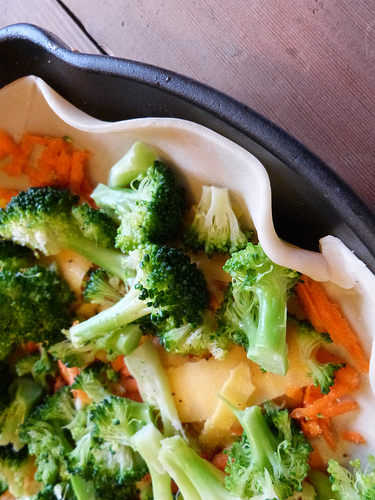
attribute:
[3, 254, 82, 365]
broccoli spear — green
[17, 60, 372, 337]
dish — white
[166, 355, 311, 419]
cheese — white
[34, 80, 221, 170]
dish — black